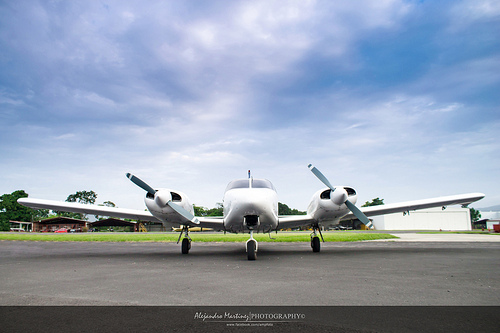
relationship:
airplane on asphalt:
[17, 163, 485, 259] [207, 251, 326, 302]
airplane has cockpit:
[17, 163, 485, 259] [225, 175, 277, 232]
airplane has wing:
[17, 163, 485, 259] [283, 185, 484, 231]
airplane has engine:
[17, 163, 485, 259] [124, 165, 205, 238]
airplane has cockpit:
[17, 163, 485, 259] [218, 168, 280, 233]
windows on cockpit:
[224, 178, 278, 194] [222, 172, 280, 192]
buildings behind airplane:
[0, 216, 137, 232] [17, 163, 485, 259]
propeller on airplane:
[122, 167, 207, 231] [17, 163, 485, 259]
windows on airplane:
[224, 178, 278, 194] [1, 137, 496, 262]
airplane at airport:
[17, 163, 485, 259] [22, 151, 484, 305]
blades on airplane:
[307, 163, 375, 230] [17, 163, 485, 259]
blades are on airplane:
[307, 163, 375, 230] [220, 154, 422, 243]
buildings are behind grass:
[0, 217, 141, 234] [0, 230, 397, 240]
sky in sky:
[0, 0, 499, 211] [17, 10, 489, 194]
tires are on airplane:
[172, 229, 334, 266] [14, 156, 491, 261]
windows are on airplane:
[228, 177, 276, 194] [17, 163, 485, 259]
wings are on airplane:
[13, 188, 490, 227] [14, 156, 491, 261]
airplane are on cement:
[17, 163, 485, 259] [14, 230, 488, 285]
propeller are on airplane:
[125, 172, 201, 224] [17, 166, 484, 255]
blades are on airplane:
[307, 163, 375, 230] [17, 166, 484, 255]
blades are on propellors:
[302, 159, 379, 232] [117, 165, 370, 258]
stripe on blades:
[307, 162, 315, 169] [307, 163, 375, 230]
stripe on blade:
[125, 171, 134, 181] [124, 170, 158, 197]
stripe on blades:
[364, 220, 373, 229] [307, 163, 375, 230]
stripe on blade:
[190, 215, 201, 223] [166, 200, 198, 224]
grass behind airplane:
[0, 230, 400, 242] [15, 141, 483, 252]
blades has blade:
[307, 163, 375, 230] [302, 154, 338, 190]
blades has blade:
[307, 163, 375, 230] [342, 198, 374, 236]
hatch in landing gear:
[167, 215, 188, 245] [168, 215, 204, 255]